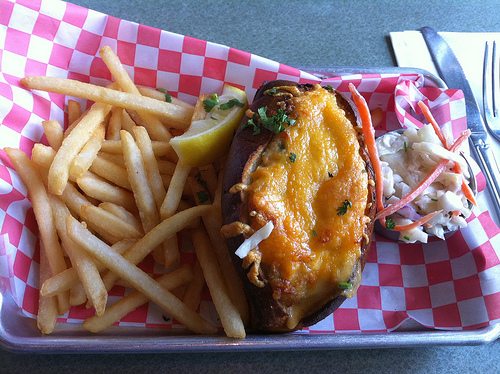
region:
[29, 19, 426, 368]
potato and french fries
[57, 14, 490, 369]
fries potato and coleslaw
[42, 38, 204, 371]
thin french fries on a plate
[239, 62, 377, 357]
a loaded baked potato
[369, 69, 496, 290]
a small cup of coleslaw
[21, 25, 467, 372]
a silver pan with paper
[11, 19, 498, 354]
a red and white checker paper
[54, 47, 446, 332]
a lemon on top of fries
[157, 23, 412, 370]
a lemon next to a potato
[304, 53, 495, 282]
a cup of coleslaw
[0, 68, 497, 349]
Food tray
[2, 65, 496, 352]
Food on a gray tray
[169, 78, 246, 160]
A slice of yellow lemon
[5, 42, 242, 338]
A side order of fries with a lemon on top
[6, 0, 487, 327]
Red and white checkered tray cover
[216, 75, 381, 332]
A twice baked sweet potato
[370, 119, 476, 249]
A small container of cole slaw with long julienne carrots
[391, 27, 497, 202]
Knife and fork on a white napkin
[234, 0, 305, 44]
Small section gray table top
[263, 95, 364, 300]
Sweet potato filling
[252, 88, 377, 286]
Potato on a plate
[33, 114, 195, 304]
French fries in a tray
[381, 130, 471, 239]
coleslaw on a tray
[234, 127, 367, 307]
potato with cheese on it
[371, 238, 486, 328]
paper wrapper in a tray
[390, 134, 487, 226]
coleslaw with carrot in it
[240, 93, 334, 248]
chives on a potato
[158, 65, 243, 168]
Lemon in a tray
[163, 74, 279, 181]
slice of Lemon in a tray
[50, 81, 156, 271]
French fries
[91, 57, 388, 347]
french fries and a loaded baked potato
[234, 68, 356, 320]
the loaded baked potato has cheese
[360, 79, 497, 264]
a side of coleslaw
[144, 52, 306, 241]
this is a lemon wedge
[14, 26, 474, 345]
food in a basket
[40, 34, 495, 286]
fries, coleslaw and a potato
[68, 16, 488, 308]
the paper is red and white checkers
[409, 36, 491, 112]
a fork and a knife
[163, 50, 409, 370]
the cheese has melted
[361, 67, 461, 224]
the coleslaw has carrots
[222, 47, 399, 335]
a baked potato with cheese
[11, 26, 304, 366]
pile of french fries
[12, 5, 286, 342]
a lemon on top of french fry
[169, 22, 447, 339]
lemon next to potato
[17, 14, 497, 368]
food on a plate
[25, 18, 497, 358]
food on a silver plate